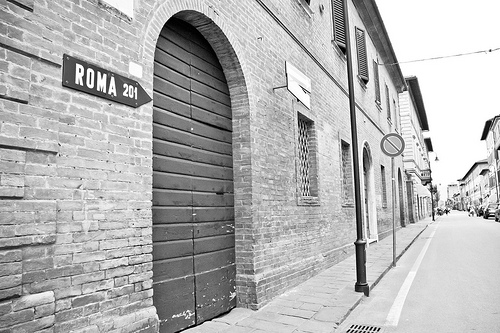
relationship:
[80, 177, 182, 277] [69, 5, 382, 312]
brick on building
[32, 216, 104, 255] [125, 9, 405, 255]
brick on building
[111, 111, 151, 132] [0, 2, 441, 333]
brick on brick building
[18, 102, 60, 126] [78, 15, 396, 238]
brick on building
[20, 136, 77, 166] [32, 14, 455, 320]
brick on brick building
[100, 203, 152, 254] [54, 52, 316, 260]
brick on building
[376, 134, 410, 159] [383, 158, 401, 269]
sign with pole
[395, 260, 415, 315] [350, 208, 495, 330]
line on road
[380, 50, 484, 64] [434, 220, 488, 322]
cable crossing street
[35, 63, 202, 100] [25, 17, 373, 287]
arrow on building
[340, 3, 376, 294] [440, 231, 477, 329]
lamp pole on street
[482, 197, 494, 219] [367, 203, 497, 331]
car parked on street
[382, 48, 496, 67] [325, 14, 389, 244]
cable going from building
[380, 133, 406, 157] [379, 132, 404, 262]
sign on pole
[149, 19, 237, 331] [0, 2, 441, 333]
door to brick building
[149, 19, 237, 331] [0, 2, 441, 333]
door on brick building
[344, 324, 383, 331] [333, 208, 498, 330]
sewer grate on road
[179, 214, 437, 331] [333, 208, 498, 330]
sidewalk alongside road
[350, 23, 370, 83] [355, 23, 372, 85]
shutters on window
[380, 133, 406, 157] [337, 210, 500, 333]
sign on road